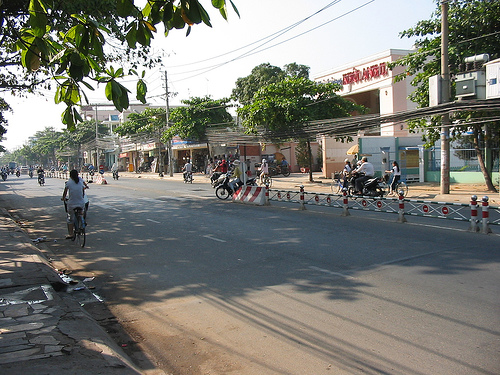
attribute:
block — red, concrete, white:
[231, 183, 267, 205]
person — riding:
[64, 168, 87, 236]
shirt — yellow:
[230, 167, 242, 178]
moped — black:
[217, 177, 251, 198]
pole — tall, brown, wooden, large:
[436, 1, 452, 194]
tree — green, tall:
[231, 64, 309, 98]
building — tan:
[252, 49, 436, 174]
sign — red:
[343, 62, 388, 88]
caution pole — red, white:
[264, 181, 272, 205]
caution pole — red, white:
[299, 184, 306, 208]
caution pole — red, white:
[341, 185, 352, 218]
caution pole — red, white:
[396, 190, 408, 223]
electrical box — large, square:
[425, 74, 443, 109]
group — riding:
[339, 153, 407, 196]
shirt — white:
[68, 178, 85, 204]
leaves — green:
[255, 75, 272, 84]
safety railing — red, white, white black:
[265, 185, 496, 233]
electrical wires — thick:
[193, 108, 498, 147]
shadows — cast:
[26, 185, 485, 298]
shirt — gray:
[184, 161, 193, 174]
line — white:
[143, 215, 162, 225]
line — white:
[204, 233, 228, 248]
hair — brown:
[69, 166, 81, 183]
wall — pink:
[321, 134, 361, 181]